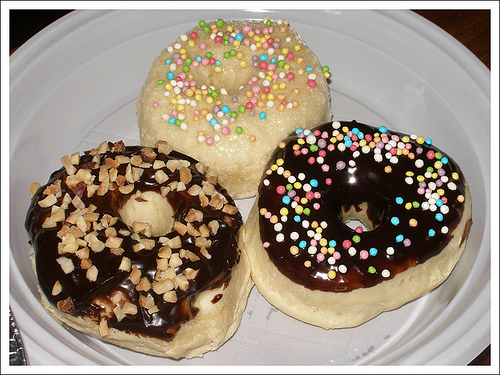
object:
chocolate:
[26, 142, 241, 342]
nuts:
[100, 320, 107, 337]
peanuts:
[53, 257, 74, 276]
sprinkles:
[177, 124, 186, 132]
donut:
[137, 16, 336, 200]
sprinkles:
[286, 248, 302, 257]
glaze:
[206, 136, 216, 146]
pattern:
[230, 302, 365, 364]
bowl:
[11, 12, 497, 368]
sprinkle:
[322, 62, 333, 81]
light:
[342, 165, 363, 189]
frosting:
[439, 226, 450, 232]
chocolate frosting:
[306, 155, 409, 251]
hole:
[116, 190, 176, 236]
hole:
[205, 57, 259, 88]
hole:
[333, 186, 393, 232]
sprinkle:
[234, 121, 245, 137]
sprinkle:
[351, 231, 362, 244]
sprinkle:
[181, 54, 195, 67]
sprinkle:
[282, 179, 295, 193]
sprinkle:
[215, 17, 226, 28]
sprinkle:
[241, 23, 253, 33]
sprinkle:
[260, 24, 273, 35]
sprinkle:
[272, 182, 288, 197]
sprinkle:
[303, 189, 316, 202]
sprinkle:
[340, 236, 354, 252]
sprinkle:
[165, 114, 178, 126]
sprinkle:
[256, 110, 270, 121]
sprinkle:
[166, 70, 180, 81]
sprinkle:
[434, 211, 445, 225]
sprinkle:
[427, 227, 437, 238]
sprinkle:
[177, 30, 189, 44]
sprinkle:
[211, 131, 222, 146]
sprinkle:
[272, 221, 285, 233]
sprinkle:
[445, 178, 458, 194]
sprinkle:
[288, 230, 300, 241]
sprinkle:
[271, 40, 281, 50]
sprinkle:
[250, 53, 259, 63]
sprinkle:
[212, 104, 223, 114]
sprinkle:
[374, 140, 385, 150]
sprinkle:
[401, 235, 412, 249]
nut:
[51, 254, 76, 279]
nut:
[178, 163, 194, 186]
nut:
[151, 167, 170, 184]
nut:
[68, 194, 87, 211]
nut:
[114, 151, 131, 165]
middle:
[119, 185, 178, 239]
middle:
[208, 60, 256, 91]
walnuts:
[85, 269, 97, 284]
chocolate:
[259, 119, 464, 294]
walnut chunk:
[165, 251, 182, 269]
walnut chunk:
[171, 218, 187, 235]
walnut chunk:
[196, 190, 209, 210]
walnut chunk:
[208, 193, 225, 212]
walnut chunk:
[199, 245, 209, 259]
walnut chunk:
[174, 270, 191, 292]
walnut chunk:
[208, 218, 221, 237]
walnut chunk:
[184, 220, 200, 235]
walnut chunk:
[193, 235, 213, 248]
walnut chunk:
[182, 266, 201, 283]